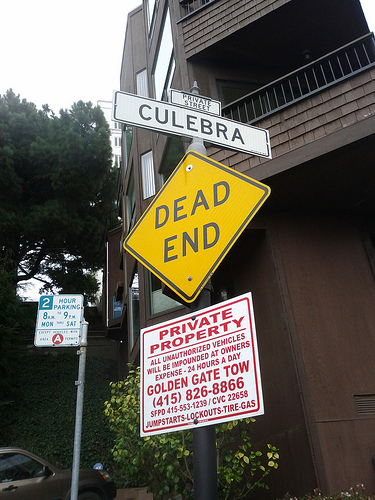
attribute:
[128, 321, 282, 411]
sign — white, square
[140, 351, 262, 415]
writing — red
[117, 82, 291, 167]
street sign — white, black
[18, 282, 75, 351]
sign — parking hours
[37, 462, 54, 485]
sedan — brown, parked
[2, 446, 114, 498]
vehicle — gold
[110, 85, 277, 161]
sign — street, black, white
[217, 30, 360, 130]
railing — black, metal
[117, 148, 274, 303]
sign — dead end, yellow, black